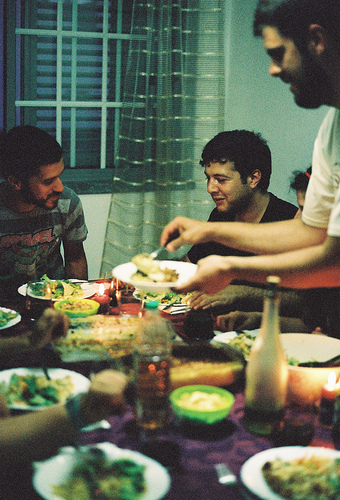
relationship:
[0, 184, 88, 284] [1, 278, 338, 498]
shirt at dinner table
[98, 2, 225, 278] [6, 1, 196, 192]
curtain on side of window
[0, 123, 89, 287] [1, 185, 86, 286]
man in striped shirt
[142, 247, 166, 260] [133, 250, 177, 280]
utensil under food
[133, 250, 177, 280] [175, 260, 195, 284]
food on plate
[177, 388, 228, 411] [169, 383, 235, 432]
food in bowl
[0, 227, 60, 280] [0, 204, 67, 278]
logo on shirt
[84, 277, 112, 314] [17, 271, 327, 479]
candle on table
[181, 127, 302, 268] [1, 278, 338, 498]
man seated at a dinner table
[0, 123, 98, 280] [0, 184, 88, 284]
man in a shirt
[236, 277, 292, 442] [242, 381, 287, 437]
bottle of wine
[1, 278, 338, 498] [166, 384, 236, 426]
dinner table full of food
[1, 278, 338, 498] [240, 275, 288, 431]
dinner table full of drink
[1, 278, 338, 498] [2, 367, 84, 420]
dinner table full of food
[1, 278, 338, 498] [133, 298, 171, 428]
dinner table full of drink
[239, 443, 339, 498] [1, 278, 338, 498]
plate on dinner table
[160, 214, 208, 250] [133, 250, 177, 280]
hand serving food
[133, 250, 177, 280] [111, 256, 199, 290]
food on plate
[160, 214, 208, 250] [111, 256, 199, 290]
hand serving plate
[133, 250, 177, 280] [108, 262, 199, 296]
food on plate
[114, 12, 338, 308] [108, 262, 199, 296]
man holding plate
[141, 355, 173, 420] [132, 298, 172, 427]
liquid in plastic bottle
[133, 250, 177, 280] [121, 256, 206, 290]
food on plate